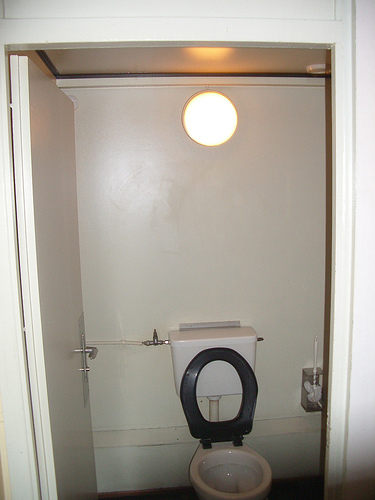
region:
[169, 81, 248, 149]
small light in bathroom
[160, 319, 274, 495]
white toilet in bathroom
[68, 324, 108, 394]
metal handle of door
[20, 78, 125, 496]
white door of bathroom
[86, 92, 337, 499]
white wall of bathroom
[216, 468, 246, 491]
water sitting in toilet bowl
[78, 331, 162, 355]
pipe along bathroom wall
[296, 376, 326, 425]
toilet brush on wall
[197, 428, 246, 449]
black hinges of toilet seat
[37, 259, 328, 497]
a small bathroom area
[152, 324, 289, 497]
a toilet in the bathroom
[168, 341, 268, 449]
a black toilet seat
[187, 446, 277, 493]
a white toilet bowl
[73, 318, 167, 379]
a pipe for the toilet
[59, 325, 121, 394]
a handle on a door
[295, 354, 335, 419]
a rack for a toilet paper brush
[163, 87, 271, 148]
a light in the bathroom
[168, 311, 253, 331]
a spot on the wall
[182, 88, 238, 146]
A bright light on the wall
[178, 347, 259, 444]
Black toilet seat in upright position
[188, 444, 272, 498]
Rim of the white porcelain toilet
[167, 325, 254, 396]
White tank of the toilet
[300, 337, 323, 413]
Toilet cleaning brush in a holster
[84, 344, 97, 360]
Silver handle of a door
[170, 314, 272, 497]
A white toilet in the bathroom with it's seat up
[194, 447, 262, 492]
Bowl of the toilet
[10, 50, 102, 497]
White door of the bathroom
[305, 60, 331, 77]
Smoke alarm in the bathroom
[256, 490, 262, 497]
part of a toilet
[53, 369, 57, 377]
part of a door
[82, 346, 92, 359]
part of a handle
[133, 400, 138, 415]
part of a wall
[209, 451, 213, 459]
part of a seat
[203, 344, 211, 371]
part of a tank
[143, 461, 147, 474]
part of a wall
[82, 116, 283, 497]
whtie wall of bathroom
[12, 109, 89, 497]
white door of bathroom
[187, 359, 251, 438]
black seat of white toilet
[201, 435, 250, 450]
black hinges on seat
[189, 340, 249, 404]
white tank of toilet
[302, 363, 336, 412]
toilet brush on wall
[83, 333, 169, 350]
small pipe on wall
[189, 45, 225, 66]
light reflecting on ceiling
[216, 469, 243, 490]
water in toilet bowl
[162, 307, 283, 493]
toilet with the lid up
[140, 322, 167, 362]
silver piping by toilet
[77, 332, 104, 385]
lever door handle on door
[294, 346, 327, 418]
brush in the brush holder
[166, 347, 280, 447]
Toilet seat on toilet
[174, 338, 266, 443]
Black toilet seat on toilet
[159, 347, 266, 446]
Toilet seat turned up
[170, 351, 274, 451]
Black toilet seat turned up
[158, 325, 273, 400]
Toilet tank on wall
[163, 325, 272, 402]
White toilet tank on wall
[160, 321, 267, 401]
Toilet tank on white wall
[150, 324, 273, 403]
White toilet tank on white wall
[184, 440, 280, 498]
Toilet bowl on toilet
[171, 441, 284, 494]
White toilet bowl on toilet